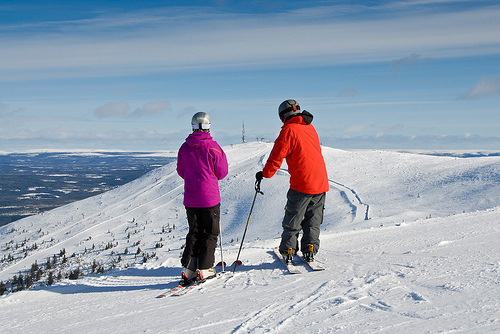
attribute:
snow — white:
[7, 137, 499, 334]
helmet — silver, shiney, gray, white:
[190, 106, 214, 134]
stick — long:
[232, 174, 261, 266]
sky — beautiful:
[3, 2, 498, 139]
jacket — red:
[259, 117, 336, 200]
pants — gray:
[274, 194, 326, 263]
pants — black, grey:
[181, 206, 221, 268]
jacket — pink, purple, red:
[174, 130, 229, 208]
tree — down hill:
[66, 261, 87, 283]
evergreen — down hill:
[96, 264, 105, 275]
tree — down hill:
[155, 241, 166, 251]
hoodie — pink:
[181, 129, 214, 148]